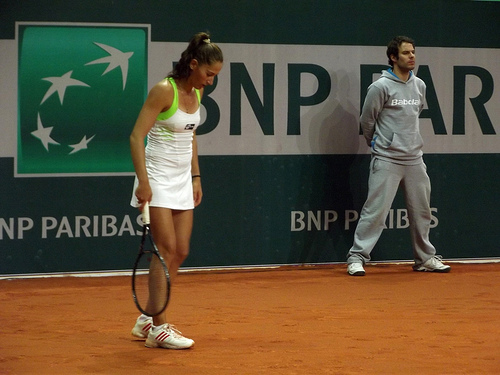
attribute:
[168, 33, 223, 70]
hair — pony tail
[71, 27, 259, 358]
woman — playing tennis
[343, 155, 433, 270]
pants — gray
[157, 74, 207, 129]
straps — green 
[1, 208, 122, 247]
letter — white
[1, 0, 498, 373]
tennis court — dirty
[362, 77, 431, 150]
shirt — gray